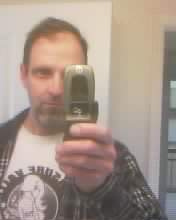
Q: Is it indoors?
A: Yes, it is indoors.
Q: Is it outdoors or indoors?
A: It is indoors.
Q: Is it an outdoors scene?
A: No, it is indoors.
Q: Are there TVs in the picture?
A: No, there are no tvs.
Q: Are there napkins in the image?
A: No, there are no napkins.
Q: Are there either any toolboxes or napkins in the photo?
A: No, there are no napkins or toolboxes.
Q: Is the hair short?
A: Yes, the hair is short.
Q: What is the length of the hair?
A: The hair is short.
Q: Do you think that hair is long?
A: No, the hair is short.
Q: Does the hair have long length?
A: No, the hair is short.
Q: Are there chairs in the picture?
A: No, there are no chairs.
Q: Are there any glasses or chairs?
A: No, there are no chairs or glasses.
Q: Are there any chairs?
A: No, there are no chairs.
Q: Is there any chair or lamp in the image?
A: No, there are no chairs or lamps.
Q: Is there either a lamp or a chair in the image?
A: No, there are no chairs or lamps.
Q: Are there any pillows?
A: No, there are no pillows.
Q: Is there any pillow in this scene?
A: No, there are no pillows.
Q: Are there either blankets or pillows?
A: No, there are no pillows or blankets.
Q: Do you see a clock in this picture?
A: No, there are no clocks.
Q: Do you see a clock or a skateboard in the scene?
A: No, there are no clocks or skateboards.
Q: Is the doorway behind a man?
A: Yes, the doorway is behind a man.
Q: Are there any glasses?
A: No, there are no glasses.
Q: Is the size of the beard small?
A: Yes, the beard is small.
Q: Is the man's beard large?
A: No, the beard is small.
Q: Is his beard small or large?
A: The beard is small.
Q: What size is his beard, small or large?
A: The beard is small.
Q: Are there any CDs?
A: No, there are no cds.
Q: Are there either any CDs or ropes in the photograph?
A: No, there are no CDs or ropes.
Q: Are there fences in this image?
A: No, there are no fences.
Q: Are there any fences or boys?
A: No, there are no fences or boys.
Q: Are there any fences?
A: No, there are no fences.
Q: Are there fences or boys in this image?
A: No, there are no fences or boys.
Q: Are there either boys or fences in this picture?
A: No, there are no fences or boys.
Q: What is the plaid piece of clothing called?
A: The clothing item is a shirt.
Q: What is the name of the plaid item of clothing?
A: The clothing item is a shirt.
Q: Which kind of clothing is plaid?
A: The clothing is a shirt.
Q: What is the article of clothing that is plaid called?
A: The clothing item is a shirt.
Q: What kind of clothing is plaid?
A: The clothing is a shirt.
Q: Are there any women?
A: No, there are no women.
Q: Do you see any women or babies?
A: No, there are no women or babies.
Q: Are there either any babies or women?
A: No, there are no women or babies.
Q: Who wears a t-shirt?
A: The man wears a t-shirt.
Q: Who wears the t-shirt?
A: The man wears a t-shirt.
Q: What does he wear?
A: The man wears a t-shirt.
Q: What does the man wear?
A: The man wears a t-shirt.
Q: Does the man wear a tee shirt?
A: Yes, the man wears a tee shirt.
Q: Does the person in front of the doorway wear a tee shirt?
A: Yes, the man wears a tee shirt.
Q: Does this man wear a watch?
A: No, the man wears a tee shirt.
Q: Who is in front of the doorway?
A: The man is in front of the doorway.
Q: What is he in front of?
A: The man is in front of the doorway.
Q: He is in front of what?
A: The man is in front of the doorway.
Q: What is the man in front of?
A: The man is in front of the doorway.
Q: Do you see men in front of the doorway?
A: Yes, there is a man in front of the doorway.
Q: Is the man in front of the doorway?
A: Yes, the man is in front of the doorway.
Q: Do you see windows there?
A: Yes, there are windows.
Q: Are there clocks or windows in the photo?
A: Yes, there are windows.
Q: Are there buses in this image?
A: No, there are no buses.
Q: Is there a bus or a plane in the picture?
A: No, there are no buses or airplanes.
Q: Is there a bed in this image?
A: No, there are no beds.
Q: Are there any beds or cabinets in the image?
A: No, there are no beds or cabinets.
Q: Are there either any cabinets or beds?
A: No, there are no beds or cabinets.